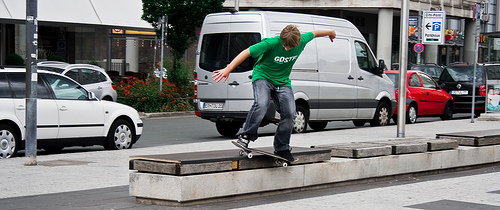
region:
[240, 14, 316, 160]
A man skating in the street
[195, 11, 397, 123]
A van on the street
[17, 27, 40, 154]
A metal pole in the photo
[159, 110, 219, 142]
a road with tarmac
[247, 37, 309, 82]
A green t-shirt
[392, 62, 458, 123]
A red car in the photo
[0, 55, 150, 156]
A white car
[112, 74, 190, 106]
Flowers on the roadside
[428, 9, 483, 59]
Buildings in the photo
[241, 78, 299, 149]
Jeans on the photo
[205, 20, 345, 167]
person skateboarding on street bench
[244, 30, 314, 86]
short sleeve green t-shirt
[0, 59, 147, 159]
white four door car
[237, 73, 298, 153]
pair of blue jeans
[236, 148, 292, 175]
whit wheels on bottom of skateboard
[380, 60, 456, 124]
two door red car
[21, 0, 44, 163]
dark grey metal pole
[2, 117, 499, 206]
grey cement sidewalk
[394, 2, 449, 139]
blue and white street sign on metal pole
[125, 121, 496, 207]
long stone steet bench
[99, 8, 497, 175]
a boy skateboarding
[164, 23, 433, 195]
a boy skateboarding next to the road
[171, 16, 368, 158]
a boy on a skateboard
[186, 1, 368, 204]
a boy wearing a shirt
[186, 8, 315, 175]
a skateboarder wearing a shirt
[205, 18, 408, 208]
a boy wearing a green shirt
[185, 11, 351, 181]
a skateboarder wearing a green shirt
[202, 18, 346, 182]
a boy wearing pants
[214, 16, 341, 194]
a skateboarder wearing pants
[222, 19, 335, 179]
a boy wearing blue jeans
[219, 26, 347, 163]
skateboarder wearing green shirt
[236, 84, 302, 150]
jeans of the skateboarder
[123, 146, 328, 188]
bench skater is skateboarding on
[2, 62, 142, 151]
white car parked on street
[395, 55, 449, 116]
red car parked on street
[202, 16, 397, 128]
van parked on the street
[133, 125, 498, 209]
row of benches on sidewalk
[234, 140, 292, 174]
black skateboard with white wheels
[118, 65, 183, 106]
flowers growing by street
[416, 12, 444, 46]
white sign on pole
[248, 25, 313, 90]
the boy is wearing a t shirt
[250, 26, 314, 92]
the t shirt is green in color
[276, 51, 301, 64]
the t shirt has a graphic print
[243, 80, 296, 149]
the boy is wearing jeans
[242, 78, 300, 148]
the jeans are blue in color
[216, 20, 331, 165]
the boy is skateboarding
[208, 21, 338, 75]
the boy has his arms extended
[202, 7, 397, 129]
the van is white in color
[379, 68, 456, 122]
the car is red in color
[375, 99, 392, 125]
the tire is black in color